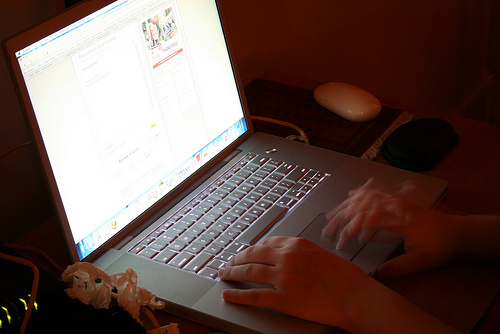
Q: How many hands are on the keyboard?
A: Two.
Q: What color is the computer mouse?
A: White.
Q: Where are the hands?
A: On the laptop.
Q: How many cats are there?
A: Zero.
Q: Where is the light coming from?
A: The computer screen.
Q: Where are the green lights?
A: To the left of the computer.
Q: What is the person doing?
A: Using a computer.